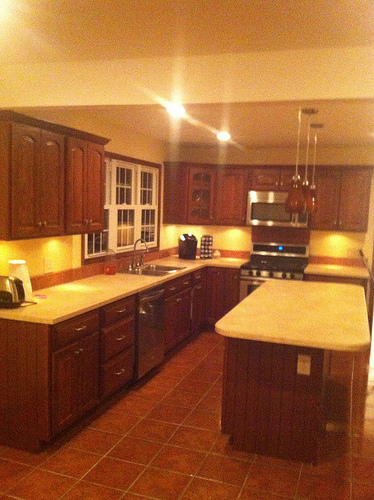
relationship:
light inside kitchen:
[167, 104, 186, 120] [1, 1, 371, 499]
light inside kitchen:
[217, 131, 231, 142] [1, 1, 371, 499]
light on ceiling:
[167, 104, 186, 120] [0, 1, 373, 147]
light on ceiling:
[217, 131, 231, 142] [0, 1, 373, 147]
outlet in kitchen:
[41, 254, 54, 274] [1, 1, 371, 499]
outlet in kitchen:
[295, 354, 311, 377] [1, 1, 371, 499]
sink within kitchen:
[117, 262, 186, 279] [1, 1, 371, 499]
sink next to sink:
[117, 268, 171, 279] [145, 265, 182, 272]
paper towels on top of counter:
[9, 259, 35, 302] [0, 251, 371, 325]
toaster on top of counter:
[1, 276, 26, 307] [0, 251, 371, 325]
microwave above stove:
[243, 190, 309, 228] [239, 242, 309, 304]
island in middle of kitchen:
[213, 278, 370, 464] [1, 1, 371, 499]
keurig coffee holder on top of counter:
[199, 233, 215, 257] [0, 251, 371, 325]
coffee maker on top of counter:
[178, 233, 199, 258] [0, 251, 371, 325]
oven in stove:
[238, 279, 264, 302] [239, 242, 309, 304]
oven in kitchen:
[238, 279, 264, 302] [1, 1, 371, 499]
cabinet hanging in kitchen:
[1, 111, 111, 242] [1, 1, 371, 499]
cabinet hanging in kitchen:
[165, 159, 215, 224] [1, 1, 371, 499]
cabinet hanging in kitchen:
[248, 162, 314, 193] [1, 1, 371, 499]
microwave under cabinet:
[243, 190, 309, 228] [248, 162, 314, 193]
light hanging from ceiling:
[284, 103, 306, 215] [0, 1, 373, 147]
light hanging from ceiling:
[300, 122, 312, 212] [0, 1, 373, 147]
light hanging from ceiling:
[307, 133, 317, 214] [0, 1, 373, 147]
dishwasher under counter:
[137, 287, 164, 383] [0, 251, 371, 325]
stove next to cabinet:
[239, 242, 309, 304] [206, 267, 238, 328]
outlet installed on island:
[295, 354, 311, 377] [213, 278, 370, 464]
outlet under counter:
[295, 354, 311, 377] [212, 278, 373, 351]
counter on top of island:
[212, 278, 373, 351] [213, 278, 370, 464]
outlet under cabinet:
[41, 254, 54, 274] [1, 111, 111, 242]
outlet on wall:
[41, 254, 54, 274] [0, 234, 79, 288]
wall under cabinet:
[0, 234, 79, 288] [1, 111, 111, 242]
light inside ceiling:
[167, 104, 186, 120] [0, 1, 373, 147]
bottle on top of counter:
[102, 248, 119, 274] [0, 251, 371, 325]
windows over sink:
[83, 157, 160, 255] [117, 262, 186, 279]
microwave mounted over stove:
[243, 190, 309, 228] [239, 242, 309, 304]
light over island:
[284, 103, 306, 215] [213, 278, 370, 464]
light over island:
[300, 122, 312, 212] [213, 278, 370, 464]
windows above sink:
[83, 157, 160, 255] [117, 262, 186, 279]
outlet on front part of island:
[41, 254, 54, 274] [213, 278, 370, 464]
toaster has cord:
[1, 276, 26, 307] [20, 301, 37, 310]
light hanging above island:
[284, 103, 306, 215] [213, 278, 370, 464]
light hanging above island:
[300, 122, 312, 212] [213, 278, 370, 464]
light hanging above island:
[307, 133, 317, 214] [213, 278, 370, 464]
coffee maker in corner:
[178, 233, 199, 258] [171, 226, 221, 268]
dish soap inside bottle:
[104, 265, 118, 275] [102, 248, 119, 274]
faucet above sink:
[130, 238, 149, 268] [117, 262, 186, 279]